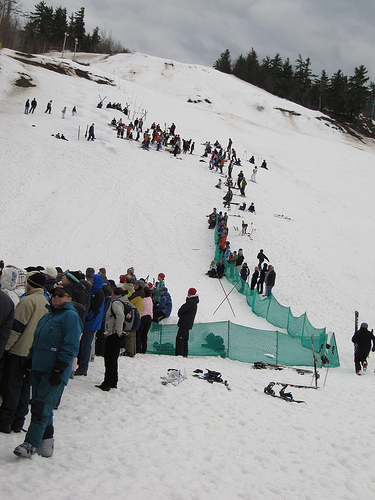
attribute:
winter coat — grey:
[202, 150, 225, 170]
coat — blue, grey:
[154, 292, 175, 318]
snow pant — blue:
[23, 367, 65, 448]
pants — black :
[351, 343, 370, 368]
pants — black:
[102, 333, 123, 389]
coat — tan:
[2, 288, 49, 358]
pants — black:
[0, 348, 36, 433]